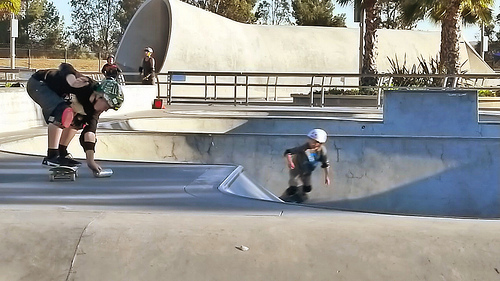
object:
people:
[137, 45, 155, 84]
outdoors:
[0, 1, 495, 279]